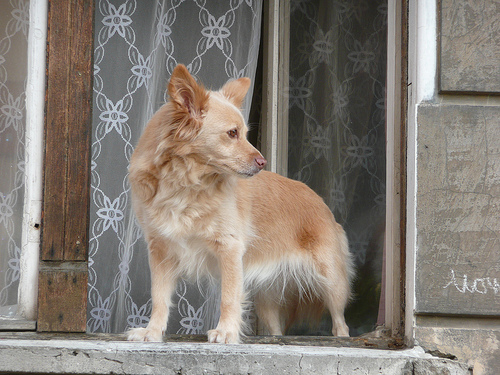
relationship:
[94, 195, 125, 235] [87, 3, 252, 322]
flower on curtain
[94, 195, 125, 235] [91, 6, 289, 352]
flower on curtain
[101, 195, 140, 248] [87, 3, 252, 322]
flower on curtain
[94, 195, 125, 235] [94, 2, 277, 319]
flower on curtain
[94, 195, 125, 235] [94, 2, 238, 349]
flower on curtain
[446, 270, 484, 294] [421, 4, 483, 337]
writing on wall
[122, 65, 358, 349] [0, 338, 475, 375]
dog on ledge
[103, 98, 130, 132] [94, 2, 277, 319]
flower design on curtain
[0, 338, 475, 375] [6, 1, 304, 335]
ledge of window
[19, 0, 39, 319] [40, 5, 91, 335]
edging near beam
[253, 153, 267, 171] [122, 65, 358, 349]
nose on dog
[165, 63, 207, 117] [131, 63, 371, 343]
ear on dog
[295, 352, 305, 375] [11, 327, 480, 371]
crack in cement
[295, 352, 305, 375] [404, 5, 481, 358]
crack on wall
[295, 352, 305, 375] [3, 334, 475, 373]
crack on ledge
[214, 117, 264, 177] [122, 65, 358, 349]
face of dog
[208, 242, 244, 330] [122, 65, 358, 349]
leg of dog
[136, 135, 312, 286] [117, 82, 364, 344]
fur of dog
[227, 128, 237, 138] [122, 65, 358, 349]
eye of dog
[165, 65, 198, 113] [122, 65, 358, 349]
ear of dog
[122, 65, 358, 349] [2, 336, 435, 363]
dog on floor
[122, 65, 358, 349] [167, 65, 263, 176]
dog turning head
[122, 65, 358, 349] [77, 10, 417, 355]
dog standing in window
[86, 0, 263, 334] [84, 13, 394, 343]
curtain in window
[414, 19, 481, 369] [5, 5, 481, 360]
siding on building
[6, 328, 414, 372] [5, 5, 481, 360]
ledge outside building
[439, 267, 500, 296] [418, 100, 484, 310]
writing on brick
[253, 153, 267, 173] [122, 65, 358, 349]
nose of dog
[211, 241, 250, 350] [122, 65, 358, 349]
leg of dog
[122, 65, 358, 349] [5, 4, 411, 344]
dog standing in window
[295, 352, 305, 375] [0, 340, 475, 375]
crack in cement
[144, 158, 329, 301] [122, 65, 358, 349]
hair on dog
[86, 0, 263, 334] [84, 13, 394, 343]
curtain hanging in window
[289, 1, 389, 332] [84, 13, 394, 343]
curtain hanging in window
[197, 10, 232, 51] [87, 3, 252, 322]
flower design adorning curtain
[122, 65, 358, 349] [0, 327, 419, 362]
dog in window sill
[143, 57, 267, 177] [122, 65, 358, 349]
head on dog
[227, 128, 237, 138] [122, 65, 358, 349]
eye on dog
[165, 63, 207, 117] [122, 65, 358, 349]
ear on dog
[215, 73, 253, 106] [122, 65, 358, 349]
left ear on dog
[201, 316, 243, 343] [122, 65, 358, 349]
paw on dog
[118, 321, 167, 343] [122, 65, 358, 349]
paw on dog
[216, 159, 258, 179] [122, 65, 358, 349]
mouth on dog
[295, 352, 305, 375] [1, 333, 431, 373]
crack on concrete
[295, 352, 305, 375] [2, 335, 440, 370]
crack on concrete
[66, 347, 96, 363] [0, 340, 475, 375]
crack on cement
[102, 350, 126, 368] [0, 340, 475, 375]
crack on cement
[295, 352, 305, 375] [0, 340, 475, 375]
crack on cement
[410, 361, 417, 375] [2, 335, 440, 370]
crack on concrete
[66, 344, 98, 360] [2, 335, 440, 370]
crack on concrete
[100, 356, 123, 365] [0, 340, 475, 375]
crack on cement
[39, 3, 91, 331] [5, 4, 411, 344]
wood on window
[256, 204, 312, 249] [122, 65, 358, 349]
fur on dog